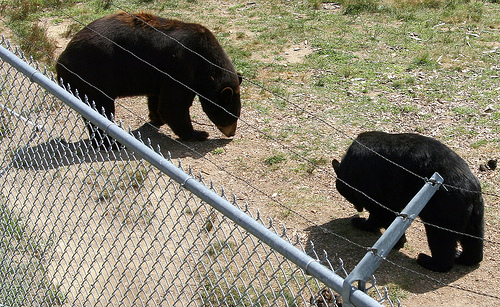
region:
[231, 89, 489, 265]
the bear has fur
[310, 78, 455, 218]
the bear has fur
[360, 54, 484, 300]
the bear has fur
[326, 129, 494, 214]
the bear has fur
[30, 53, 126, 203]
Chain link fence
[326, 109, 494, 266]
young black bear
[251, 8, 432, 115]
flat ground surface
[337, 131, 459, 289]
barb wire support bracket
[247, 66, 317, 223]
barbed wire fence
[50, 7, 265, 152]
an adult black bear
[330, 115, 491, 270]
a young bear walking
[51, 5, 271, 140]
an adult black bear walking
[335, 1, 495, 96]
green foliage on the ground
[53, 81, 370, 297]
chain link fence with barb wire top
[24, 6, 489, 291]
black bears in a cage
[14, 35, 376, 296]
metal fence enclosure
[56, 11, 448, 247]
rocky ground with patches of grass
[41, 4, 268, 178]
bear with its nose to the ground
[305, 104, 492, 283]
small black bear standing on dirt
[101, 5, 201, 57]
patch of brown fur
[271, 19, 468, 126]
rocks and dirt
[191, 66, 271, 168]
light brown snout of a bear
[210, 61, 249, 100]
tiny round ears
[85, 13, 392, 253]
set of three wires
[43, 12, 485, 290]
THE BEARS ARE BLACK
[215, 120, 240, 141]
THE BEAR HAS A BROWN MUZZLE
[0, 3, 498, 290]
THE GRASS IS GREEN AND PATCHY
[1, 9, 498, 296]
THE DIRT IS BROWN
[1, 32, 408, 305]
THE FENCE IS CHAIN LINK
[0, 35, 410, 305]
THE FENCE IS GREY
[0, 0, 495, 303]
THE BARBED WIRE IS AT THE TOP OF THE FENCE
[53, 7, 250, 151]
THE BEAR IS BIG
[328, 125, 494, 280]
THE BEAR IS SMALL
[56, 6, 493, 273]
THE BEARS ARE SNIFFING THE GROUND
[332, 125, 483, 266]
Brown bear behind a fence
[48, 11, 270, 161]
Brown bear with it head bowed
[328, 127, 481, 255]
Brown bear looking down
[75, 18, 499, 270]
Two brown bears standing next to each other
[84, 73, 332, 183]
Metal fence with barbed wire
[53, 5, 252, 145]
Brown bear with perked ears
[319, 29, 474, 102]
Dusty ground with low grass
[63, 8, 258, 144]
Brown bear looking at the ground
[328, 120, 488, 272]
Brown bear moving forward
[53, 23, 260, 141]
Brown bear with light brown nose.